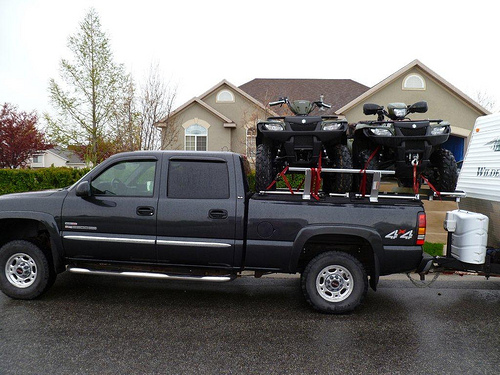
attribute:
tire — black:
[301, 247, 375, 314]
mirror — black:
[71, 173, 96, 198]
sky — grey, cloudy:
[127, 7, 384, 75]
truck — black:
[0, 151, 425, 316]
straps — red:
[313, 163, 351, 186]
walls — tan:
[185, 71, 485, 197]